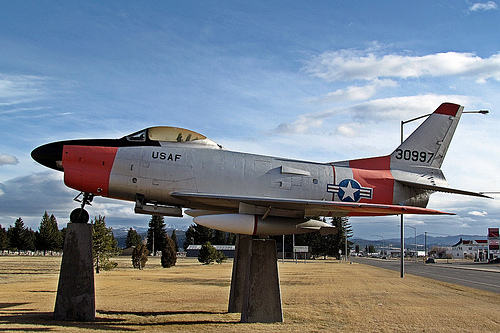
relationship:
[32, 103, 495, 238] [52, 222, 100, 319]
plane sitting on pillar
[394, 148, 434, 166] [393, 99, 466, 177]
number painted on wing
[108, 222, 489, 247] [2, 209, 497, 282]
mountains visible in background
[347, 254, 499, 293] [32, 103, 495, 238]
road next to plane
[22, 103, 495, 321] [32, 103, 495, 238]
display has jet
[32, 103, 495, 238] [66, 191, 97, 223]
jet has front landing gear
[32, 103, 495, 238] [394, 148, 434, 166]
jet has number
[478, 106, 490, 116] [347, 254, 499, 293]
street light over street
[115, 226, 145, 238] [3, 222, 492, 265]
mountain visible in distance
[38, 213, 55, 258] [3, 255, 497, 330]
tree bordering park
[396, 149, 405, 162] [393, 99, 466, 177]
3 painted on tail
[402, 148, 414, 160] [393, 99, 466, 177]
0 painted on tail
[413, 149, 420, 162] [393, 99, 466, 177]
9 painted on tail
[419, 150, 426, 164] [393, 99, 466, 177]
9 painted on tail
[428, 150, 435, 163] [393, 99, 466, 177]
7 painted on tail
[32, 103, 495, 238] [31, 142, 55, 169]
plane has nose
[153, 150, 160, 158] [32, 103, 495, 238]
u painted on plane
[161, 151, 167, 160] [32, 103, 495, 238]
s painted on plane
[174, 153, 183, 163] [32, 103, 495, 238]
f painted on plane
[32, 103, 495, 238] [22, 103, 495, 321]
plane sitting on display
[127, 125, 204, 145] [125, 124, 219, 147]
dome over cockpit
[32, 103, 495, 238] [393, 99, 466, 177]
plane has tail